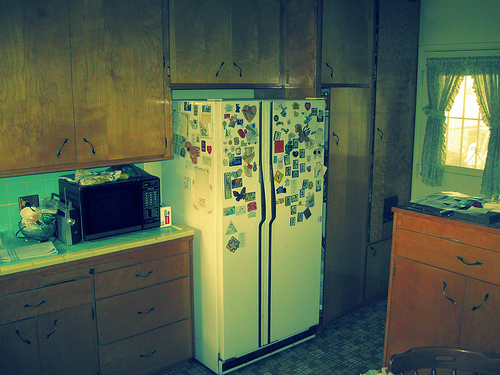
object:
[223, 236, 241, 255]
stickers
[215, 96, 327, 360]
fridge door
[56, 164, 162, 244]
microwave oven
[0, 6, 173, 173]
cabinets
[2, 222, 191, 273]
countertop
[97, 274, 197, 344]
drawers